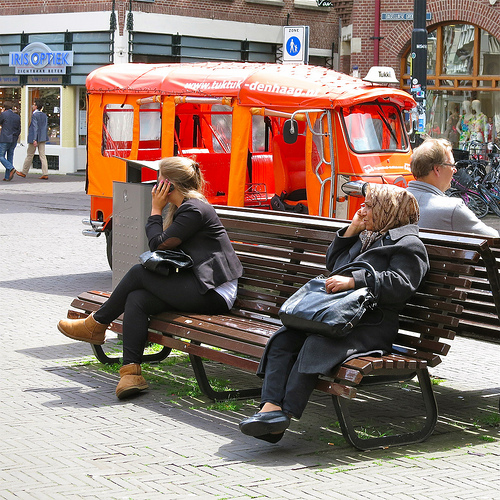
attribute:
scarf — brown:
[368, 183, 421, 231]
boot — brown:
[54, 313, 110, 347]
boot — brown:
[113, 358, 151, 401]